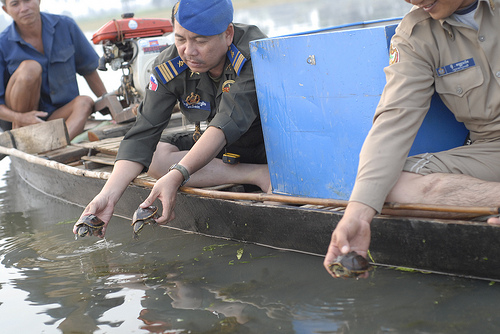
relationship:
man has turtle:
[70, 0, 268, 237] [76, 213, 107, 241]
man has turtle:
[70, 0, 268, 237] [130, 205, 160, 239]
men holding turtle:
[322, 1, 499, 282] [330, 251, 373, 282]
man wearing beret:
[70, 0, 268, 237] [177, 1, 235, 36]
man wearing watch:
[70, 0, 268, 237] [169, 161, 191, 184]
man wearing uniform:
[70, 0, 268, 237] [113, 24, 274, 169]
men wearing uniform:
[322, 1, 499, 282] [348, 0, 500, 216]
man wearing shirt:
[0, 0, 110, 144] [0, 12, 103, 122]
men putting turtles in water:
[0, 1, 497, 280] [0, 154, 499, 332]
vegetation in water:
[204, 237, 257, 266] [0, 154, 499, 332]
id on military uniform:
[435, 54, 478, 80] [348, 0, 500, 216]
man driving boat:
[0, 0, 110, 144] [0, 11, 497, 283]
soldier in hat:
[70, 0, 268, 237] [177, 1, 235, 36]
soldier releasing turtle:
[70, 0, 268, 237] [76, 213, 107, 241]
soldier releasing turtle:
[70, 0, 268, 237] [130, 205, 160, 239]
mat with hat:
[70, 0, 268, 237] [177, 1, 235, 36]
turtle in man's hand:
[76, 213, 107, 241] [73, 194, 115, 245]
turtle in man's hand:
[130, 205, 160, 239] [141, 175, 181, 228]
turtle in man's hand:
[330, 251, 373, 282] [324, 216, 374, 281]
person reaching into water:
[70, 0, 268, 237] [0, 154, 499, 332]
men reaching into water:
[322, 1, 499, 282] [0, 154, 499, 332]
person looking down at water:
[70, 0, 268, 237] [0, 154, 499, 332]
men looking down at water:
[322, 1, 499, 282] [0, 154, 499, 332]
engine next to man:
[92, 11, 175, 99] [0, 0, 110, 144]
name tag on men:
[435, 54, 478, 80] [322, 1, 499, 282]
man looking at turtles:
[0, 0, 110, 144] [73, 206, 160, 240]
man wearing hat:
[70, 0, 268, 237] [177, 1, 235, 36]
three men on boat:
[0, 1, 497, 280] [0, 11, 497, 283]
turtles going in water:
[75, 204, 373, 282] [0, 154, 499, 332]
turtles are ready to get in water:
[75, 204, 373, 282] [0, 154, 499, 332]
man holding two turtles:
[70, 0, 268, 237] [73, 206, 160, 240]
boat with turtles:
[0, 11, 497, 283] [75, 204, 373, 282]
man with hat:
[70, 0, 268, 237] [177, 1, 235, 36]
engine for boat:
[92, 11, 175, 99] [0, 11, 497, 283]